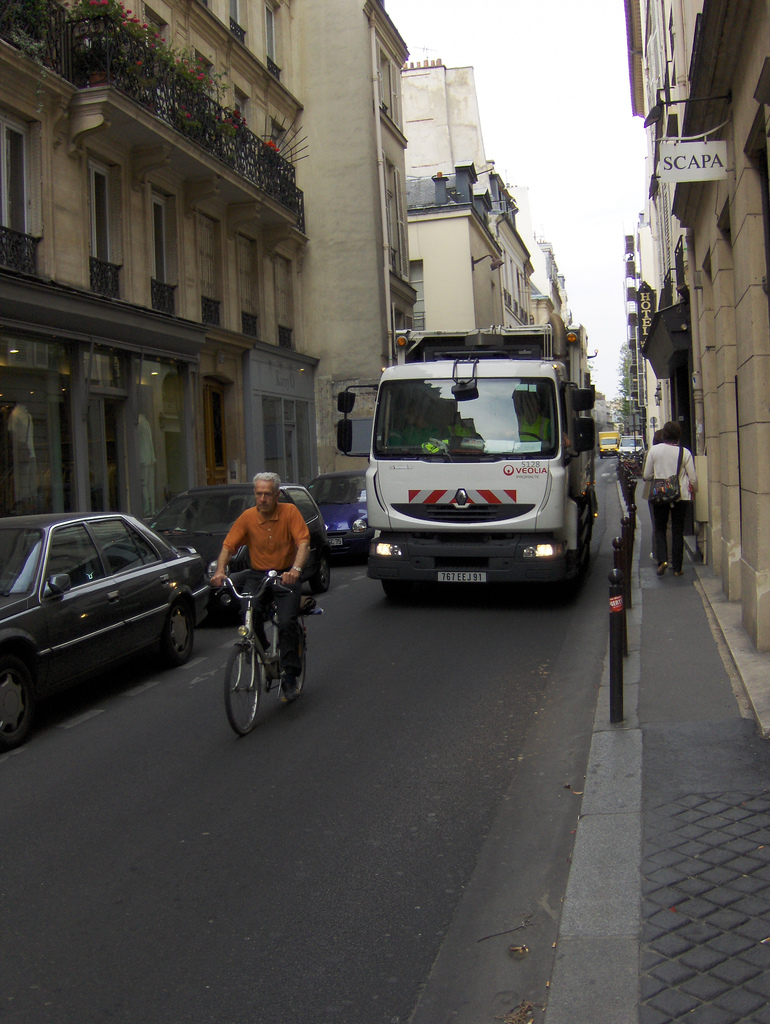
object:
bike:
[198, 551, 325, 737]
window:
[371, 378, 561, 465]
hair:
[252, 473, 280, 497]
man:
[211, 471, 312, 699]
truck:
[336, 323, 595, 603]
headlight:
[368, 539, 402, 559]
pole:
[608, 564, 625, 726]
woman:
[643, 421, 697, 579]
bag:
[647, 446, 684, 504]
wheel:
[223, 638, 262, 737]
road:
[0, 427, 770, 1024]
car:
[0, 510, 205, 757]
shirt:
[211, 504, 309, 589]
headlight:
[521, 540, 562, 560]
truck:
[599, 430, 620, 458]